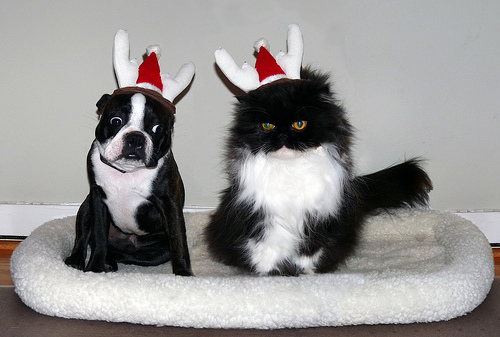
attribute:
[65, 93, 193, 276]
animal — pictured, dog, sitting, black, white, little, bug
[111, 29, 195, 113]
hat — santa hat, red, little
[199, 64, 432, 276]
animal — pictured, cat, black, white, fluffy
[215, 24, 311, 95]
hat — santa hat, red, little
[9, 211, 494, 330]
bed — white, soft, fluffy, plush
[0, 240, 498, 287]
ground — wooden, hardwood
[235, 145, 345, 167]
neck — white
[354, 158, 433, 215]
tail — black, fluffy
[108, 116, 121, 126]
eye — black, white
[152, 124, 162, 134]
eye — black, white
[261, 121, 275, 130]
eye — black, orange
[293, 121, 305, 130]
eye — black, orange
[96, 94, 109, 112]
ear — black